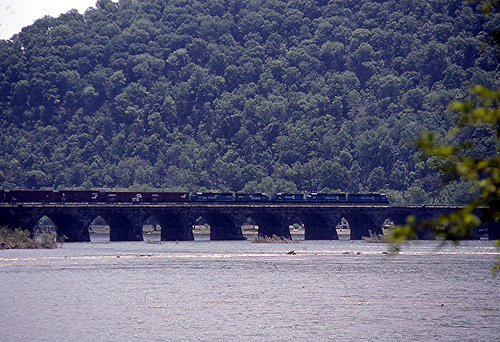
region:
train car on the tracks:
[345, 186, 396, 204]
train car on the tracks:
[302, 188, 350, 206]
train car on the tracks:
[266, 189, 311, 207]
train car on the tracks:
[236, 186, 270, 208]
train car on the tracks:
[187, 188, 234, 204]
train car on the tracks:
[138, 187, 193, 207]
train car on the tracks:
[95, 186, 143, 206]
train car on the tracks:
[50, 186, 103, 210]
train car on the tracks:
[0, 185, 63, 203]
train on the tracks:
[2, 187, 399, 217]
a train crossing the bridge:
[2, 182, 396, 212]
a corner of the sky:
[2, 2, 87, 29]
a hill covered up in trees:
[8, 5, 497, 203]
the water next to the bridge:
[6, 238, 496, 335]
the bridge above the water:
[6, 204, 487, 242]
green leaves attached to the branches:
[370, 81, 497, 288]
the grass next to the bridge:
[0, 227, 59, 246]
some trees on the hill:
[58, 55, 323, 150]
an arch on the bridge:
[135, 210, 188, 242]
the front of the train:
[348, 187, 387, 204]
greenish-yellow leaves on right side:
[389, 0, 495, 265]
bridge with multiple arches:
[0, 194, 498, 244]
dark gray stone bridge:
[1, 189, 497, 242]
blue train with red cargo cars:
[0, 177, 392, 205]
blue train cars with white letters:
[191, 185, 383, 206]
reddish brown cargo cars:
[1, 180, 192, 204]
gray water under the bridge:
[1, 227, 495, 339]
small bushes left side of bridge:
[1, 224, 56, 255]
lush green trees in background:
[0, 0, 498, 221]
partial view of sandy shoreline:
[83, 208, 405, 239]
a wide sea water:
[131, 264, 225, 315]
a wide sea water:
[180, 273, 265, 313]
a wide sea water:
[175, 261, 223, 296]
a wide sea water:
[240, 260, 300, 315]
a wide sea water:
[170, 271, 273, 332]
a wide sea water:
[125, 226, 248, 313]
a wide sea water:
[187, 325, 223, 335]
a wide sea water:
[181, 301, 254, 337]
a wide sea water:
[167, 265, 272, 335]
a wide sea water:
[168, 282, 230, 326]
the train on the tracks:
[3, 182, 403, 210]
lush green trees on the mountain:
[81, 31, 365, 152]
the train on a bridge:
[8, 183, 403, 208]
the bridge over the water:
[6, 204, 499, 247]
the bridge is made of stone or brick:
[9, 202, 499, 247]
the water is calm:
[182, 265, 463, 329]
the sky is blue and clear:
[13, 4, 38, 17]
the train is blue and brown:
[193, 192, 384, 205]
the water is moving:
[143, 239, 365, 338]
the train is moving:
[8, 184, 402, 209]